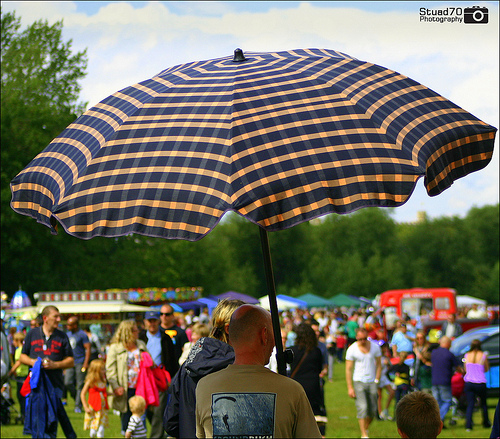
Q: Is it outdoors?
A: Yes, it is outdoors.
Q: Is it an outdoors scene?
A: Yes, it is outdoors.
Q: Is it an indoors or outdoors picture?
A: It is outdoors.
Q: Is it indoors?
A: No, it is outdoors.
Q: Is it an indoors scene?
A: No, it is outdoors.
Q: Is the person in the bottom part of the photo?
A: Yes, the person is in the bottom of the image.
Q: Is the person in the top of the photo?
A: No, the person is in the bottom of the image.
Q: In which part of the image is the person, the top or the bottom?
A: The person is in the bottom of the image.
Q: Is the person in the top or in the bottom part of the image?
A: The person is in the bottom of the image.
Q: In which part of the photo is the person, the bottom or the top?
A: The person is in the bottom of the image.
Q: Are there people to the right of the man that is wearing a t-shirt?
A: Yes, there is a person to the right of the man.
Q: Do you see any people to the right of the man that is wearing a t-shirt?
A: Yes, there is a person to the right of the man.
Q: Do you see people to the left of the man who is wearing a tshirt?
A: No, the person is to the right of the man.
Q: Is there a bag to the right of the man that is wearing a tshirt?
A: No, there is a person to the right of the man.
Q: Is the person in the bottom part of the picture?
A: Yes, the person is in the bottom of the image.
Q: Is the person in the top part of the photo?
A: No, the person is in the bottom of the image.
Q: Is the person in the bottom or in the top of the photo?
A: The person is in the bottom of the image.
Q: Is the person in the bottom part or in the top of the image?
A: The person is in the bottom of the image.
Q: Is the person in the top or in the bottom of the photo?
A: The person is in the bottom of the image.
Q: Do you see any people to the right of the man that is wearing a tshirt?
A: Yes, there is a person to the right of the man.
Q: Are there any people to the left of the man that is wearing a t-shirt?
A: No, the person is to the right of the man.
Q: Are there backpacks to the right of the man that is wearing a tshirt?
A: No, there is a person to the right of the man.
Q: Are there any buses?
A: Yes, there is a bus.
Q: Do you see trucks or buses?
A: Yes, there is a bus.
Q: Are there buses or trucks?
A: Yes, there is a bus.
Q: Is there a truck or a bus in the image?
A: Yes, there is a bus.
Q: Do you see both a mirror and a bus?
A: No, there is a bus but no mirrors.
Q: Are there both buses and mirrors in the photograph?
A: No, there is a bus but no mirrors.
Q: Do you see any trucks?
A: No, there are no trucks.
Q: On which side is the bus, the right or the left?
A: The bus is on the right of the image.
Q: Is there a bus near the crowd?
A: Yes, there is a bus near the crowd.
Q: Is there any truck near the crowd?
A: No, there is a bus near the crowd.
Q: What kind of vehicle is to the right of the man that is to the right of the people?
A: The vehicle is a bus.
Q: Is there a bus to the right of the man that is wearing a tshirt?
A: Yes, there is a bus to the right of the man.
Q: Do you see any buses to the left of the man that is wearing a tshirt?
A: No, the bus is to the right of the man.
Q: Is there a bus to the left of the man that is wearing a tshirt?
A: No, the bus is to the right of the man.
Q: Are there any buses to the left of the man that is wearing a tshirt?
A: No, the bus is to the right of the man.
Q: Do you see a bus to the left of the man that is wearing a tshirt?
A: No, the bus is to the right of the man.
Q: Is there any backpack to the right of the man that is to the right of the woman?
A: No, there is a bus to the right of the man.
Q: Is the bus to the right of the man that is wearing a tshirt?
A: Yes, the bus is to the right of the man.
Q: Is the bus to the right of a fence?
A: No, the bus is to the right of the man.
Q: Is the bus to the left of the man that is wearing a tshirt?
A: No, the bus is to the right of the man.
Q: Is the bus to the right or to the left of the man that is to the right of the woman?
A: The bus is to the right of the man.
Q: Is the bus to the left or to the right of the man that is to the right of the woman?
A: The bus is to the right of the man.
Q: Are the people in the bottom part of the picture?
A: Yes, the people are in the bottom of the image.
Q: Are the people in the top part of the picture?
A: No, the people are in the bottom of the image.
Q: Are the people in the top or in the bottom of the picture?
A: The people are in the bottom of the image.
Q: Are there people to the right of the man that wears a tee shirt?
A: Yes, there are people to the right of the man.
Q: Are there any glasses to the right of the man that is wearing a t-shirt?
A: No, there are people to the right of the man.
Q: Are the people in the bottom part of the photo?
A: Yes, the people are in the bottom of the image.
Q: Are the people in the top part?
A: No, the people are in the bottom of the image.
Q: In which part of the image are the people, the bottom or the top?
A: The people are in the bottom of the image.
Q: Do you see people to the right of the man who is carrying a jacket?
A: Yes, there are people to the right of the man.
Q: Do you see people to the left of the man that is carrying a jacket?
A: No, the people are to the right of the man.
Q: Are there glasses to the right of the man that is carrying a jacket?
A: No, there are people to the right of the man.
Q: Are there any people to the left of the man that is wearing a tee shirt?
A: Yes, there are people to the left of the man.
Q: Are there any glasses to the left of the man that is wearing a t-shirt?
A: No, there are people to the left of the man.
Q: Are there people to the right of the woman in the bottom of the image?
A: Yes, there are people to the right of the woman.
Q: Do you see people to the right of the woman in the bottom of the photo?
A: Yes, there are people to the right of the woman.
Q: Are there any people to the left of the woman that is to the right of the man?
A: No, the people are to the right of the woman.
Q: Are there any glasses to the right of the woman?
A: No, there are people to the right of the woman.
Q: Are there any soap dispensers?
A: No, there are no soap dispensers.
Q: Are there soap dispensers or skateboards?
A: No, there are no soap dispensers or skateboards.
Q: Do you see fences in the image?
A: No, there are no fences.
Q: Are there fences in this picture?
A: No, there are no fences.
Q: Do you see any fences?
A: No, there are no fences.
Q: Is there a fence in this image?
A: No, there are no fences.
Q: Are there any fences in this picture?
A: No, there are no fences.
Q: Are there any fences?
A: No, there are no fences.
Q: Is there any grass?
A: Yes, there is grass.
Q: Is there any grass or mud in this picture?
A: Yes, there is grass.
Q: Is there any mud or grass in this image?
A: Yes, there is grass.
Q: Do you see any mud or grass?
A: Yes, there is grass.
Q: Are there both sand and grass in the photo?
A: No, there is grass but no sand.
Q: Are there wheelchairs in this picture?
A: No, there are no wheelchairs.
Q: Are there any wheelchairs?
A: No, there are no wheelchairs.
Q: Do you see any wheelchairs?
A: No, there are no wheelchairs.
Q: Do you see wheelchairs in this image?
A: No, there are no wheelchairs.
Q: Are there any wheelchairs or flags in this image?
A: No, there are no wheelchairs or flags.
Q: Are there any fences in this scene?
A: No, there are no fences.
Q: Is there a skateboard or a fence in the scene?
A: No, there are no fences or skateboards.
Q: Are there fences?
A: No, there are no fences.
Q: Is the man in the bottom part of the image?
A: Yes, the man is in the bottom of the image.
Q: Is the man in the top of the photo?
A: No, the man is in the bottom of the image.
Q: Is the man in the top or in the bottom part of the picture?
A: The man is in the bottom of the image.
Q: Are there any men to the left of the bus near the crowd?
A: Yes, there is a man to the left of the bus.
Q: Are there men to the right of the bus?
A: No, the man is to the left of the bus.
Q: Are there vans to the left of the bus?
A: No, there is a man to the left of the bus.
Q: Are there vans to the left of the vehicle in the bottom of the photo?
A: No, there is a man to the left of the bus.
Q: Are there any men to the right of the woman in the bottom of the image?
A: Yes, there is a man to the right of the woman.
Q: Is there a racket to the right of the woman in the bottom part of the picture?
A: No, there is a man to the right of the woman.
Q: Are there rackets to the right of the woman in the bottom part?
A: No, there is a man to the right of the woman.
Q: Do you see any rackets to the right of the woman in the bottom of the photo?
A: No, there is a man to the right of the woman.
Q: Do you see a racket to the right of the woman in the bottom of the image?
A: No, there is a man to the right of the woman.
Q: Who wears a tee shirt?
A: The man wears a tee shirt.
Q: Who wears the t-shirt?
A: The man wears a tee shirt.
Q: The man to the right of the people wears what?
A: The man wears a t-shirt.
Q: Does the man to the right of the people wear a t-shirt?
A: Yes, the man wears a t-shirt.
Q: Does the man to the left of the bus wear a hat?
A: No, the man wears a t-shirt.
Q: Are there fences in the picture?
A: No, there are no fences.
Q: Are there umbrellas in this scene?
A: Yes, there is an umbrella.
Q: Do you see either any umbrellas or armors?
A: Yes, there is an umbrella.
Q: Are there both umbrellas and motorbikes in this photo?
A: No, there is an umbrella but no motorcycles.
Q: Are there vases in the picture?
A: No, there are no vases.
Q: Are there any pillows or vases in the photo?
A: No, there are no vases or pillows.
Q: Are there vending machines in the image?
A: No, there are no vending machines.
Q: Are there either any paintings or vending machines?
A: No, there are no vending machines or paintings.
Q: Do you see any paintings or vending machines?
A: No, there are no vending machines or paintings.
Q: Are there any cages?
A: No, there are no cages.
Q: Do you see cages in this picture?
A: No, there are no cages.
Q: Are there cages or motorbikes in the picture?
A: No, there are no cages or motorbikes.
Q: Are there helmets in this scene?
A: No, there are no helmets.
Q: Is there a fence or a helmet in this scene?
A: No, there are no helmets or fences.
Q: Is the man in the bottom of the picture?
A: Yes, the man is in the bottom of the image.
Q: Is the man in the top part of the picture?
A: No, the man is in the bottom of the image.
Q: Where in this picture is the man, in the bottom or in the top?
A: The man is in the bottom of the image.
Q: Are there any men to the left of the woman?
A: Yes, there is a man to the left of the woman.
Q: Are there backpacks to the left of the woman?
A: No, there is a man to the left of the woman.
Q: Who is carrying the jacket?
A: The man is carrying the jacket.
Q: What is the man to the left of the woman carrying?
A: The man is carrying a jacket.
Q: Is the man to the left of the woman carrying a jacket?
A: Yes, the man is carrying a jacket.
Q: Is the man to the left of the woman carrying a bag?
A: No, the man is carrying a jacket.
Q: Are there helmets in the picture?
A: No, there are no helmets.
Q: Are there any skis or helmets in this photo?
A: No, there are no helmets or skis.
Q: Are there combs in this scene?
A: No, there are no combs.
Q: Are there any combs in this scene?
A: No, there are no combs.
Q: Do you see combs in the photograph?
A: No, there are no combs.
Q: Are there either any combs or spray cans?
A: No, there are no combs or spray cans.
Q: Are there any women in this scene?
A: Yes, there is a woman.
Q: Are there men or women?
A: Yes, there is a woman.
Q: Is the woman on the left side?
A: Yes, the woman is on the left of the image.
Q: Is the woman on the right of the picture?
A: No, the woman is on the left of the image.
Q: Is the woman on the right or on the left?
A: The woman is on the left of the image.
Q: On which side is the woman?
A: The woman is on the left of the image.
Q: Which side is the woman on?
A: The woman is on the left of the image.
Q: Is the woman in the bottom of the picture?
A: Yes, the woman is in the bottom of the image.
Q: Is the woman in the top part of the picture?
A: No, the woman is in the bottom of the image.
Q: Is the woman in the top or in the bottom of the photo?
A: The woman is in the bottom of the image.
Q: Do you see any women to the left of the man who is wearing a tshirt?
A: Yes, there is a woman to the left of the man.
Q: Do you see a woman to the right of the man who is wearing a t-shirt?
A: No, the woman is to the left of the man.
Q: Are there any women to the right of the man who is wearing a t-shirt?
A: No, the woman is to the left of the man.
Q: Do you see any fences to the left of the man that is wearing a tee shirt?
A: No, there is a woman to the left of the man.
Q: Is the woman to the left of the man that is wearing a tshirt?
A: Yes, the woman is to the left of the man.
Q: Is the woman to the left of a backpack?
A: No, the woman is to the left of the man.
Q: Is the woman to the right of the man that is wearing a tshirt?
A: No, the woman is to the left of the man.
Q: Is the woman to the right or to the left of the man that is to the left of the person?
A: The woman is to the left of the man.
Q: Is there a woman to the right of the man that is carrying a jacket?
A: Yes, there is a woman to the right of the man.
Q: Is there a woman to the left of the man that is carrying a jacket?
A: No, the woman is to the right of the man.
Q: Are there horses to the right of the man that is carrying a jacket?
A: No, there is a woman to the right of the man.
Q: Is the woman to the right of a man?
A: Yes, the woman is to the right of a man.